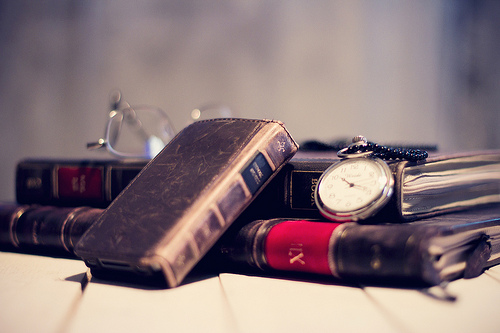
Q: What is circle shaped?
A: Clock.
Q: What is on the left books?
A: Glasses.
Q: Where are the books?
A: On a table.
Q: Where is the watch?
A: On a book.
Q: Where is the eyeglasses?
A: On a book.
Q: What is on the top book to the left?
A: Eyeglasses.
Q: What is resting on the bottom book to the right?
A: Watch.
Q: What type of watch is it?
A: Pocket watch.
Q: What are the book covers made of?
A: Leather.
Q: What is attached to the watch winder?
A: Strap.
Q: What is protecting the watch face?
A: Glass cover.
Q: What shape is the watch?
A: Round.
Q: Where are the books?
A: On a table.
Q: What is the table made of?
A: Wood.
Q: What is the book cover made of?
A: Leather.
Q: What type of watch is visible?
A: Pocket watch.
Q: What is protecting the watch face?
A: Glass cover.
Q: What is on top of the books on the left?
A: Eyeglasses.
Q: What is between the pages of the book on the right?
A: Bookmark.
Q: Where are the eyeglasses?
A: On top of the books on the left?.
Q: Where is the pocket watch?
A: On top of a book on the right?.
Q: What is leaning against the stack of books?
A: Book.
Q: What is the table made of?
A: Wood.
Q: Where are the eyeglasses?
A: On books.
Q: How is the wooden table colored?
A: Beige.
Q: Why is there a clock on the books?
A: To show time.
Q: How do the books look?
A: Antique.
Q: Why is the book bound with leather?
A: Safekeeping.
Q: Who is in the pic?
A: No one.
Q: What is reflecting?
A: Glasses.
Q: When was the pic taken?
A: During the day.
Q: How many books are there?
A: 3.